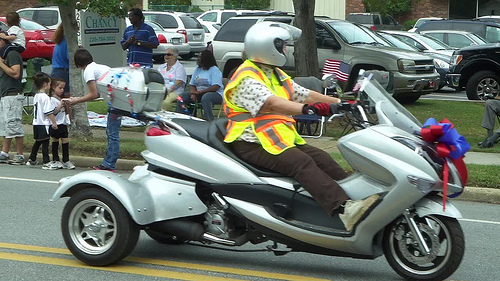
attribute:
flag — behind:
[320, 58, 353, 83]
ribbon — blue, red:
[421, 115, 468, 212]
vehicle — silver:
[48, 71, 464, 280]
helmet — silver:
[242, 18, 304, 70]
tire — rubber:
[61, 186, 142, 269]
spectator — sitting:
[181, 50, 225, 114]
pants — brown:
[222, 136, 350, 215]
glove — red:
[301, 102, 335, 117]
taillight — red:
[145, 121, 171, 139]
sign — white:
[79, 9, 129, 69]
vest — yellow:
[221, 58, 308, 154]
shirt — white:
[83, 60, 112, 91]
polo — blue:
[119, 24, 160, 66]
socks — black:
[64, 140, 70, 163]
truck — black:
[446, 41, 499, 100]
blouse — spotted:
[227, 65, 308, 144]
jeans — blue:
[101, 106, 124, 168]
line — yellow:
[2, 238, 353, 279]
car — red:
[0, 15, 59, 60]